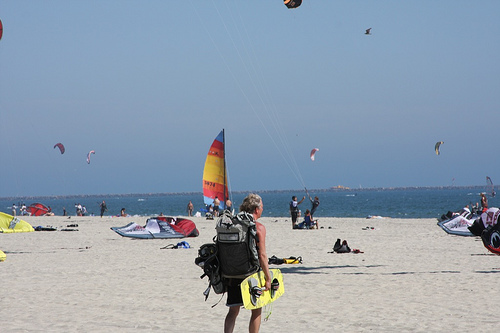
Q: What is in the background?
A: A large patch of blue sky.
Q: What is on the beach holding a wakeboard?
A: The man.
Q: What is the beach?
A: Sandy ground.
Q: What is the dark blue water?
A: Large body.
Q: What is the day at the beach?
A: Clear.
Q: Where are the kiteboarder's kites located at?
A: The air.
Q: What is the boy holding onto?
A: Kite lines.